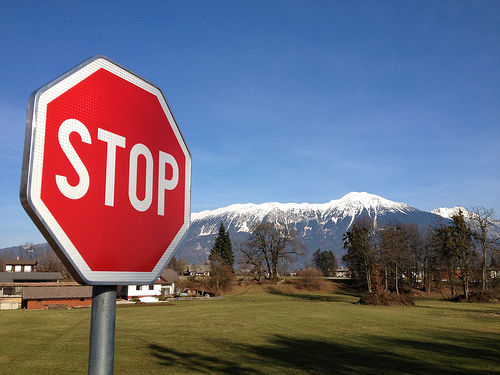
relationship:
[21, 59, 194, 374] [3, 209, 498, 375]
sign in foreground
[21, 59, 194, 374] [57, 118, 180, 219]
sign says stop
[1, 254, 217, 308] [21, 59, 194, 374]
buildings behind sign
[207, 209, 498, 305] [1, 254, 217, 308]
trees by buildings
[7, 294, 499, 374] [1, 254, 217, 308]
lawn in front of buildings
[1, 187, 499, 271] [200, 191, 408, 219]
mountain topped in snow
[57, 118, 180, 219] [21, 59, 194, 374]
stop on sign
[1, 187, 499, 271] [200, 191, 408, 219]
mountain capped in snow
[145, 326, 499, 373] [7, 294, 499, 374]
shadows on lawn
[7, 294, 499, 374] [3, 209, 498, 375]
lawn in foreground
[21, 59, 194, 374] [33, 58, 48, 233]
sign has a border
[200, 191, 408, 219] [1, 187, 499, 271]
snow covers mountain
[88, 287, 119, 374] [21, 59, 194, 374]
pole holds sign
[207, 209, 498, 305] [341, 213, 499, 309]
trees in a grove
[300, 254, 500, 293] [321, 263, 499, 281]
area neighboring buildings